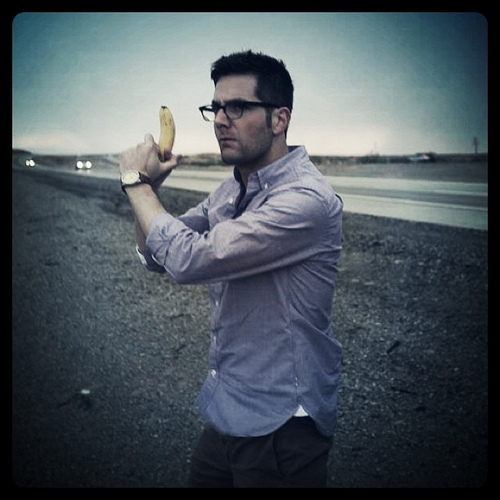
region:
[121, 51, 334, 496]
man holding a banana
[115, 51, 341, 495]
man holding a banana like a handgun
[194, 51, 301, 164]
man wearing black vision glasses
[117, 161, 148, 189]
man wearing wristwatch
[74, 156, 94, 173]
can driving on road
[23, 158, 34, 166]
can driving on road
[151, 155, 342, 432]
man wearing light purple shirt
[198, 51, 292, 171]
man with an alert facial expression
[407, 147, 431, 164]
car appears in the distance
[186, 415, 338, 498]
man wearing dark pair of pants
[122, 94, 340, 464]
man holding a banana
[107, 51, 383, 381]
man holding a banana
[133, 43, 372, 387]
man holding a banana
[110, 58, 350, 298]
man holding a banana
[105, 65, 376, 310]
man holding a banana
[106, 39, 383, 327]
man holding a banana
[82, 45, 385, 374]
man holding a banana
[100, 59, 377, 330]
man holding a banana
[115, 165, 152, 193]
a man wearing a wrist watch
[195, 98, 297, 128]
a man wearing glasses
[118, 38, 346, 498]
a man posing while holding a banana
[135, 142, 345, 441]
a man in a blue shirt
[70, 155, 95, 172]
a car driving in the background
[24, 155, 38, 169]
a car driving in the background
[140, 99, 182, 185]
a man holding a yellow banana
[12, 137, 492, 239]
a long stretch of road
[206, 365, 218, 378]
a white button on a shirt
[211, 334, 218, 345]
a white button on a shirt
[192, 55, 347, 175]
man wearing glasses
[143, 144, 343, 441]
blue shirt has a tailored hem line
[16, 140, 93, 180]
two sets of headlights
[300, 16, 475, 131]
sky is two different shades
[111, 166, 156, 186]
mans watch with brown band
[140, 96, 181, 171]
banana beign held with both hands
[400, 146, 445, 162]
vehcile in the distance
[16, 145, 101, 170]
two vehicles on the highway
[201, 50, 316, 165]
man has a shadow style beard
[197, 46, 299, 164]
man is looking straight ahead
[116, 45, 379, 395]
a man holding a banana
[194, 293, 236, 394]
three buttons in a row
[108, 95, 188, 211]
banana being held like a gun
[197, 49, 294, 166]
young man in glasses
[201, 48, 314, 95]
dark hair in a buzz cut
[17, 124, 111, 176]
cars coming down the road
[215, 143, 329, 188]
purple collard shirt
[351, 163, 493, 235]
two lane high way in the background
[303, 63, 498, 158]
not a cloud in the sky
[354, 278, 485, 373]
concrete covers the ground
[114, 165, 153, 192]
watch on a man's arm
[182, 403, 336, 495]
man's dark colored pants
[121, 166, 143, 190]
face of a watch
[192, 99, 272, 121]
glasses on a man's face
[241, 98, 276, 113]
arm on a pair of glasses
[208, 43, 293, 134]
man's dark colored hair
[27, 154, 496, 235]
roadway behind a man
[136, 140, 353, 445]
long sleeved blue shirt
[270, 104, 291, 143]
left ear of a man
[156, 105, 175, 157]
the yellow ripe banana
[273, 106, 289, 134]
the ear on the head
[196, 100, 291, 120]
the black framed eye glasses